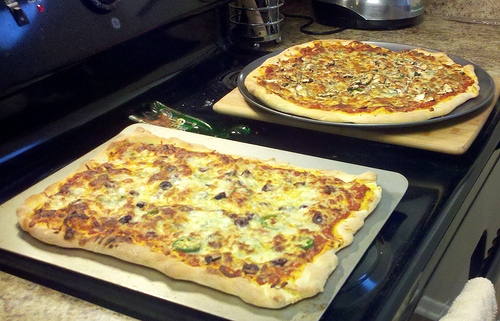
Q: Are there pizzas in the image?
A: Yes, there is a pizza.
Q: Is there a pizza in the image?
A: Yes, there is a pizza.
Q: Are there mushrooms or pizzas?
A: Yes, there is a pizza.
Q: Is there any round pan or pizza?
A: Yes, there is a round pizza.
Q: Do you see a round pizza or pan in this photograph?
A: Yes, there is a round pizza.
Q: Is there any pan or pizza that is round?
A: Yes, the pizza is round.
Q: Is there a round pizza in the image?
A: Yes, there is a round pizza.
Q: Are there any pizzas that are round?
A: Yes, there is a pizza that is round.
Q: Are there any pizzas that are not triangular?
A: Yes, there is a round pizza.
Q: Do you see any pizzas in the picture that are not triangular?
A: Yes, there is a round pizza.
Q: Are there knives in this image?
A: No, there are no knives.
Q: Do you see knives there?
A: No, there are no knives.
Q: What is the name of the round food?
A: The food is a pizza.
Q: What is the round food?
A: The food is a pizza.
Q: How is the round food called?
A: The food is a pizza.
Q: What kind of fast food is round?
A: The fast food is a pizza.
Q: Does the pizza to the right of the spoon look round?
A: Yes, the pizza is round.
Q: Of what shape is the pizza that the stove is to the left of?
A: The pizza is round.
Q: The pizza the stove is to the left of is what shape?
A: The pizza is round.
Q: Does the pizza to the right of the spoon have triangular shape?
A: No, the pizza is round.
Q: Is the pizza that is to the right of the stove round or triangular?
A: The pizza is round.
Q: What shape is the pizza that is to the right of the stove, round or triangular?
A: The pizza is round.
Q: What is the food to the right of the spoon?
A: The food is a pizza.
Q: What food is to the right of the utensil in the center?
A: The food is a pizza.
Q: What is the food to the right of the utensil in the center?
A: The food is a pizza.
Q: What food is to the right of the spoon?
A: The food is a pizza.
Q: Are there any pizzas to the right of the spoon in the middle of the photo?
A: Yes, there is a pizza to the right of the spoon.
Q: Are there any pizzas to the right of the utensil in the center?
A: Yes, there is a pizza to the right of the spoon.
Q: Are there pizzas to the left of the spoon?
A: No, the pizza is to the right of the spoon.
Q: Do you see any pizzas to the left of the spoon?
A: No, the pizza is to the right of the spoon.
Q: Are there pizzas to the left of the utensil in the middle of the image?
A: No, the pizza is to the right of the spoon.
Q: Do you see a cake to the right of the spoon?
A: No, there is a pizza to the right of the spoon.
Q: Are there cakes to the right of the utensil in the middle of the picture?
A: No, there is a pizza to the right of the spoon.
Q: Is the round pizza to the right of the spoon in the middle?
A: Yes, the pizza is to the right of the spoon.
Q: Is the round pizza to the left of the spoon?
A: No, the pizza is to the right of the spoon.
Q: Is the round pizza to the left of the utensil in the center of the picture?
A: No, the pizza is to the right of the spoon.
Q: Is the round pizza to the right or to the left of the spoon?
A: The pizza is to the right of the spoon.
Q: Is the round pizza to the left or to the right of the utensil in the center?
A: The pizza is to the right of the spoon.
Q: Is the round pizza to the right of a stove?
A: Yes, the pizza is to the right of a stove.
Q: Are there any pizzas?
A: Yes, there is a pizza.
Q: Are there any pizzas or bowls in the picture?
A: Yes, there is a pizza.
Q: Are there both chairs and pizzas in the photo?
A: No, there is a pizza but no chairs.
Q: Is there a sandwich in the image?
A: No, there are no sandwiches.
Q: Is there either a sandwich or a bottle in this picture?
A: No, there are no sandwiches or bottles.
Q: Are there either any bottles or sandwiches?
A: No, there are no sandwiches or bottles.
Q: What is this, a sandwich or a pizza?
A: This is a pizza.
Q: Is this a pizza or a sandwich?
A: This is a pizza.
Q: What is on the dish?
A: The pizza is on the dish.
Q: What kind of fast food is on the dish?
A: The food is a pizza.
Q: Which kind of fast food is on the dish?
A: The food is a pizza.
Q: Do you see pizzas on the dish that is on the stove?
A: Yes, there is a pizza on the dish.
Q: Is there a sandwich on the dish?
A: No, there is a pizza on the dish.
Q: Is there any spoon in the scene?
A: Yes, there is a spoon.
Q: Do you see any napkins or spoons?
A: Yes, there is a spoon.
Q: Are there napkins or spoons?
A: Yes, there is a spoon.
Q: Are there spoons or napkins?
A: Yes, there is a spoon.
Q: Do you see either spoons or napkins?
A: Yes, there is a spoon.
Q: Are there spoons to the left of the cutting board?
A: Yes, there is a spoon to the left of the cutting board.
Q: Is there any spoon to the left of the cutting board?
A: Yes, there is a spoon to the left of the cutting board.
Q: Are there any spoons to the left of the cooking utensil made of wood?
A: Yes, there is a spoon to the left of the cutting board.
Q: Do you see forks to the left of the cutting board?
A: No, there is a spoon to the left of the cutting board.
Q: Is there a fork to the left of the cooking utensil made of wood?
A: No, there is a spoon to the left of the cutting board.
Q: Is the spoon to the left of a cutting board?
A: Yes, the spoon is to the left of a cutting board.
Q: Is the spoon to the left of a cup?
A: No, the spoon is to the left of a cutting board.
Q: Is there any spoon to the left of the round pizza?
A: Yes, there is a spoon to the left of the pizza.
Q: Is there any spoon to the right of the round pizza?
A: No, the spoon is to the left of the pizza.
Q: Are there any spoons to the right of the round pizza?
A: No, the spoon is to the left of the pizza.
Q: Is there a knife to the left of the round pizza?
A: No, there is a spoon to the left of the pizza.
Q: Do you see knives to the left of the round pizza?
A: No, there is a spoon to the left of the pizza.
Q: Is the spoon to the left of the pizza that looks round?
A: Yes, the spoon is to the left of the pizza.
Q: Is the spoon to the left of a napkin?
A: No, the spoon is to the left of the pizza.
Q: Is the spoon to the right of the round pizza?
A: No, the spoon is to the left of the pizza.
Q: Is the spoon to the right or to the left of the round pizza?
A: The spoon is to the left of the pizza.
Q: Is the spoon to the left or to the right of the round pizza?
A: The spoon is to the left of the pizza.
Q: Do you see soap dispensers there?
A: No, there are no soap dispensers.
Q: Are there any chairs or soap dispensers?
A: No, there are no soap dispensers or chairs.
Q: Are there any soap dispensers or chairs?
A: No, there are no soap dispensers or chairs.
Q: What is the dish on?
A: The dish is on the stove.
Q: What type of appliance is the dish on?
A: The dish is on the stove.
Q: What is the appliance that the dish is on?
A: The appliance is a stove.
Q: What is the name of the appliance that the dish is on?
A: The appliance is a stove.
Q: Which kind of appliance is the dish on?
A: The dish is on the stove.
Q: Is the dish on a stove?
A: Yes, the dish is on a stove.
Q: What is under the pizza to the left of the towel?
A: The stove is under the pizza.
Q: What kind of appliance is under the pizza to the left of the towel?
A: The appliance is a stove.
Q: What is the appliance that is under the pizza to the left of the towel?
A: The appliance is a stove.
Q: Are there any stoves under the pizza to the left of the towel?
A: Yes, there is a stove under the pizza.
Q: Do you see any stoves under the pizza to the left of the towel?
A: Yes, there is a stove under the pizza.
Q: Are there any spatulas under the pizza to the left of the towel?
A: No, there is a stove under the pizza.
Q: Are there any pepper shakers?
A: No, there are no pepper shakers.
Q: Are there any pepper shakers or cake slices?
A: No, there are no pepper shakers or cake slices.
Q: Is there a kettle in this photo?
A: Yes, there is a kettle.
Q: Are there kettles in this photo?
A: Yes, there is a kettle.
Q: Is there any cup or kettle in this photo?
A: Yes, there is a kettle.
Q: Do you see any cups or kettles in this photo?
A: Yes, there is a kettle.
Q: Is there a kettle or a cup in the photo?
A: Yes, there is a kettle.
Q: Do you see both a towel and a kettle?
A: Yes, there are both a kettle and a towel.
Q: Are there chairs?
A: No, there are no chairs.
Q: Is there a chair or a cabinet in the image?
A: No, there are no chairs or cabinets.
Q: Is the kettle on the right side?
A: Yes, the kettle is on the right of the image.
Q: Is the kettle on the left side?
A: No, the kettle is on the right of the image.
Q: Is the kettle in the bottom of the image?
A: No, the kettle is in the top of the image.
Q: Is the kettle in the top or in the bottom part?
A: The kettle is in the top of the image.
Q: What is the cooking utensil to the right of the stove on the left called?
A: The cooking utensil is a kettle.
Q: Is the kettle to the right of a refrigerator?
A: No, the kettle is to the right of the stove.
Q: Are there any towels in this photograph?
A: Yes, there is a towel.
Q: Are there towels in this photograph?
A: Yes, there is a towel.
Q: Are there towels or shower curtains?
A: Yes, there is a towel.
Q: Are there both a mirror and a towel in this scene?
A: No, there is a towel but no mirrors.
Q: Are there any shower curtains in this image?
A: No, there are no shower curtains.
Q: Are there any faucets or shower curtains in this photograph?
A: No, there are no shower curtains or faucets.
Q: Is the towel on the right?
A: Yes, the towel is on the right of the image.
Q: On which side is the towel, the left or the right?
A: The towel is on the right of the image.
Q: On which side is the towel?
A: The towel is on the right of the image.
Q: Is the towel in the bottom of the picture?
A: Yes, the towel is in the bottom of the image.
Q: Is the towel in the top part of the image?
A: No, the towel is in the bottom of the image.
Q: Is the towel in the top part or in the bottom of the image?
A: The towel is in the bottom of the image.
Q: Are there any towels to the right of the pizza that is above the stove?
A: Yes, there is a towel to the right of the pizza.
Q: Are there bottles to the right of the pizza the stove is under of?
A: No, there is a towel to the right of the pizza.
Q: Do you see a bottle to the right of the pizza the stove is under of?
A: No, there is a towel to the right of the pizza.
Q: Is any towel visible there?
A: Yes, there is a towel.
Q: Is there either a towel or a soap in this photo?
A: Yes, there is a towel.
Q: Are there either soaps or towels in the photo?
A: Yes, there is a towel.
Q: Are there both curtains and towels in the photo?
A: No, there is a towel but no curtains.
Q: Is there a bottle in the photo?
A: No, there are no bottles.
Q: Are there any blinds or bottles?
A: No, there are no bottles or blinds.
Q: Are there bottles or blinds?
A: No, there are no bottles or blinds.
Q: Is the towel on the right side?
A: Yes, the towel is on the right of the image.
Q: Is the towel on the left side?
A: No, the towel is on the right of the image.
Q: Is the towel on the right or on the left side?
A: The towel is on the right of the image.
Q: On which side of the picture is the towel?
A: The towel is on the right of the image.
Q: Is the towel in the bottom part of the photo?
A: Yes, the towel is in the bottom of the image.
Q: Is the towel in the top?
A: No, the towel is in the bottom of the image.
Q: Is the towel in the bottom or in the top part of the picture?
A: The towel is in the bottom of the image.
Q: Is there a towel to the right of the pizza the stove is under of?
A: Yes, there is a towel to the right of the pizza.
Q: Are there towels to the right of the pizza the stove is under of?
A: Yes, there is a towel to the right of the pizza.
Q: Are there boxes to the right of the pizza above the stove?
A: No, there is a towel to the right of the pizza.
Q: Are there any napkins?
A: No, there are no napkins.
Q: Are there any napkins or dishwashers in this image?
A: No, there are no napkins or dishwashers.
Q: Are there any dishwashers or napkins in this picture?
A: No, there are no napkins or dishwashers.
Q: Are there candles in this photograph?
A: No, there are no candles.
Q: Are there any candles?
A: No, there are no candles.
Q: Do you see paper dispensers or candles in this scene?
A: No, there are no candles or paper dispensers.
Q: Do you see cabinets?
A: No, there are no cabinets.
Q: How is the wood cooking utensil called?
A: The cooking utensil is a cutting board.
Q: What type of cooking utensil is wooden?
A: The cooking utensil is a cutting board.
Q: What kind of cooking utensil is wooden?
A: The cooking utensil is a cutting board.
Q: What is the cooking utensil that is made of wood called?
A: The cooking utensil is a cutting board.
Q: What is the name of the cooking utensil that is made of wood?
A: The cooking utensil is a cutting board.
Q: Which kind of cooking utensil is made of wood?
A: The cooking utensil is a cutting board.